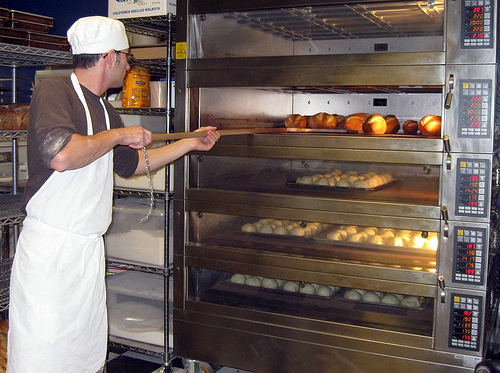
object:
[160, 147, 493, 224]
ovens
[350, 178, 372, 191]
bread dough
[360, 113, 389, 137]
bread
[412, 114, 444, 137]
bread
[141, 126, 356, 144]
paddle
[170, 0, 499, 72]
ovens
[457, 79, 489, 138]
control panel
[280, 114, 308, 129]
bread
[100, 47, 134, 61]
glasses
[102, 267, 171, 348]
plastic container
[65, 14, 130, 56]
hat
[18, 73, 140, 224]
shirt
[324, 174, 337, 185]
uncooked bread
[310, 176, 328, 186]
uncooked bread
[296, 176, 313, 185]
uncooked bread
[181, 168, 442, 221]
shelves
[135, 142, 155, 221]
chain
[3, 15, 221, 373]
chef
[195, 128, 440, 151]
rack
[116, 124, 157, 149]
hand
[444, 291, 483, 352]
control panel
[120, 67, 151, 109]
orange bag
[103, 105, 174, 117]
rack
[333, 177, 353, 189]
dough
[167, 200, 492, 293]
oven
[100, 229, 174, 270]
flour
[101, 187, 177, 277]
container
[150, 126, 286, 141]
stick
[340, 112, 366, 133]
bread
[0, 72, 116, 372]
apron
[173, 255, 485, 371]
oven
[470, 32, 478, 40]
numbers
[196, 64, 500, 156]
oven